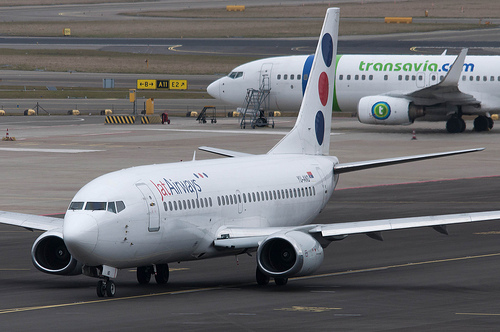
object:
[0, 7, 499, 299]
airplane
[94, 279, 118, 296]
gear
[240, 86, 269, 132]
ladder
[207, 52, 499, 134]
plane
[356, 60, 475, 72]
writing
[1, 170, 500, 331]
runway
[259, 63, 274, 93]
door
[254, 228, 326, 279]
engine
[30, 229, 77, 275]
engine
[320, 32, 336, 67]
dot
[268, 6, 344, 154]
tail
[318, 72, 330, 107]
dot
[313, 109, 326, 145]
dot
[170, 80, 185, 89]
marking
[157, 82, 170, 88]
marking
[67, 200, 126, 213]
windshield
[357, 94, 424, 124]
engine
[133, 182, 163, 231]
door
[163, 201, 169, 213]
window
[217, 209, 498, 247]
wing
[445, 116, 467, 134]
wheel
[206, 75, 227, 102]
nose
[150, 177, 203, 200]
writing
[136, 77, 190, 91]
sign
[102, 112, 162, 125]
barrier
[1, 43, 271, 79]
ground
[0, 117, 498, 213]
tarmac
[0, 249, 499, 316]
line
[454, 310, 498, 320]
line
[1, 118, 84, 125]
line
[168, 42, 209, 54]
line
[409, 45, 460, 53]
line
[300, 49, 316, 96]
stripe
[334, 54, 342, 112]
stripe